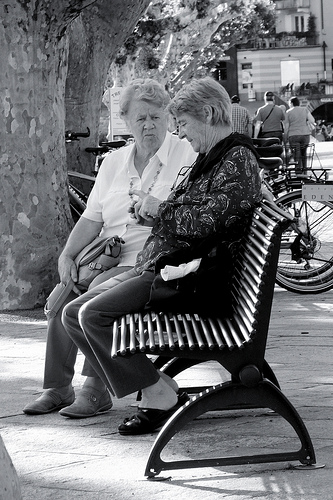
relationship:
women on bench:
[71, 79, 251, 284] [196, 206, 281, 409]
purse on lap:
[56, 233, 133, 278] [99, 233, 150, 273]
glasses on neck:
[169, 162, 194, 202] [205, 132, 241, 169]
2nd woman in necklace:
[23, 75, 262, 435] [121, 180, 165, 196]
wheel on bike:
[278, 197, 323, 283] [265, 138, 332, 272]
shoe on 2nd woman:
[108, 384, 181, 438] [161, 86, 251, 343]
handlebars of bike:
[60, 119, 97, 178] [265, 138, 332, 272]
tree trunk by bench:
[3, 17, 76, 327] [196, 206, 281, 409]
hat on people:
[262, 84, 281, 116] [231, 94, 253, 134]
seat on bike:
[96, 138, 128, 153] [265, 138, 332, 272]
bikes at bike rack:
[265, 138, 332, 272] [311, 149, 327, 176]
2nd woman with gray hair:
[23, 75, 262, 435] [128, 81, 176, 99]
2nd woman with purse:
[23, 75, 262, 435] [56, 233, 133, 278]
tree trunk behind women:
[3, 17, 76, 327] [71, 79, 251, 284]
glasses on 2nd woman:
[169, 162, 194, 202] [161, 86, 251, 343]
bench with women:
[196, 206, 281, 409] [71, 79, 251, 284]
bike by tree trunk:
[265, 138, 332, 272] [3, 17, 76, 327]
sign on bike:
[294, 180, 332, 201] [265, 138, 332, 272]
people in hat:
[231, 94, 253, 134] [262, 84, 281, 116]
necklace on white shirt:
[121, 180, 165, 196] [97, 153, 214, 257]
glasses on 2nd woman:
[169, 162, 194, 202] [23, 75, 262, 435]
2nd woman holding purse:
[23, 75, 262, 435] [56, 233, 133, 278]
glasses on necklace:
[169, 162, 194, 202] [121, 180, 165, 196]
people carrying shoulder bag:
[231, 94, 253, 134] [252, 121, 265, 142]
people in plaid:
[231, 94, 253, 134] [228, 110, 247, 137]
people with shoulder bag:
[231, 94, 253, 134] [252, 121, 265, 142]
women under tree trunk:
[71, 79, 251, 284] [3, 17, 76, 327]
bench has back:
[196, 206, 281, 409] [267, 191, 319, 465]